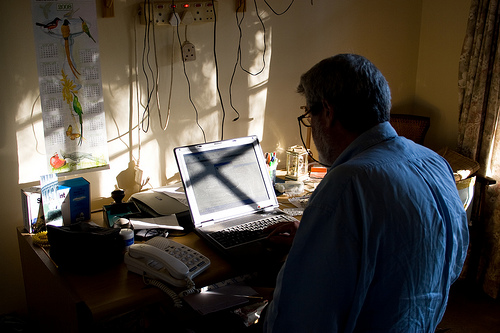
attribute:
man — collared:
[244, 30, 487, 332]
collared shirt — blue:
[256, 132, 486, 318]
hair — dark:
[311, 30, 404, 135]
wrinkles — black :
[398, 179, 467, 331]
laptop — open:
[170, 132, 301, 277]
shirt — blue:
[266, 135, 466, 330]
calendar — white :
[41, 60, 72, 156]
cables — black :
[136, 4, 292, 142]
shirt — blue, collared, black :
[257, 122, 471, 329]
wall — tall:
[2, 3, 475, 322]